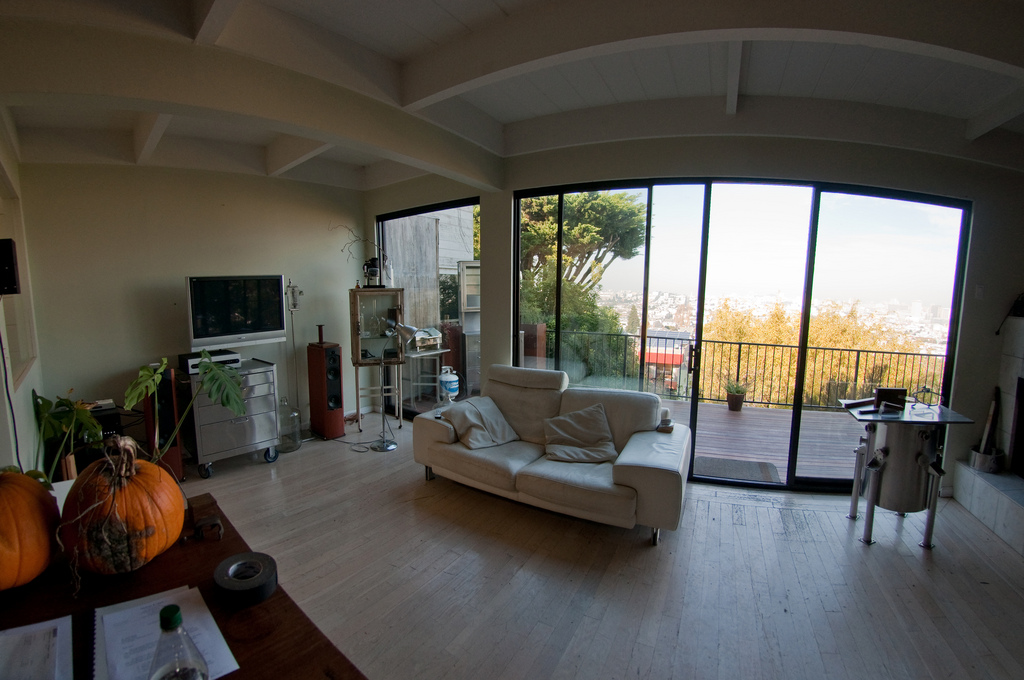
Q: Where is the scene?
A: Living room.